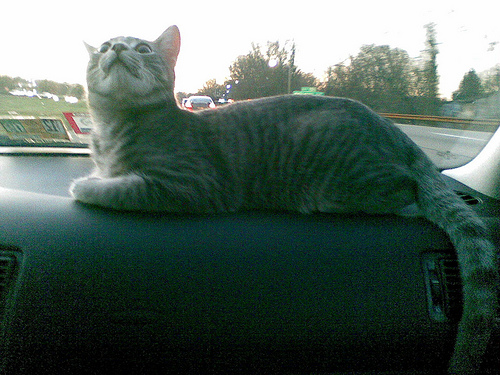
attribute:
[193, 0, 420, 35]
sky — gray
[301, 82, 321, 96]
sign — green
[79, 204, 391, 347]
dashboard — black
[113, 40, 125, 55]
nose — black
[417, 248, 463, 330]
vent — right side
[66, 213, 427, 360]
dashboard — plastic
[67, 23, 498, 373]
cat — gray, striped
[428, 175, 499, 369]
tail — large, furry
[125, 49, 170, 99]
white whiskers — large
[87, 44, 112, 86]
white whiskers — large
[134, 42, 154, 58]
eye — small, black, yellow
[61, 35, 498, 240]
cat — grey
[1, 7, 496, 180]
windshield — glass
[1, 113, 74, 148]
decal — small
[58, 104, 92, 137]
decal — small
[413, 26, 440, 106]
tree — leafy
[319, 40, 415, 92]
tree — leafy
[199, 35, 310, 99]
tree — leafy